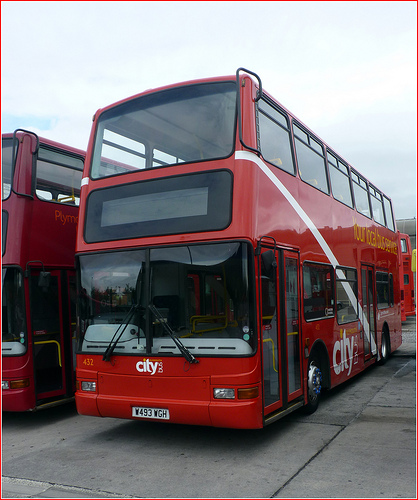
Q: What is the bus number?
A: 432.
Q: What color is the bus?
A: Red.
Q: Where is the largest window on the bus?
A: On the front.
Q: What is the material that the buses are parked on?
A: Concrete.